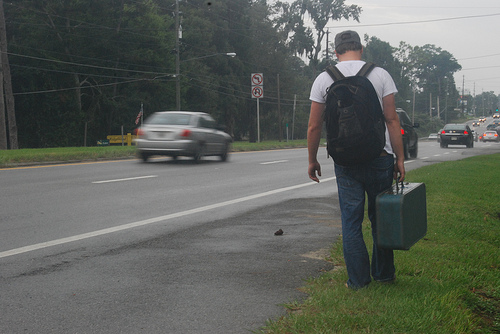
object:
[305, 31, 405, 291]
man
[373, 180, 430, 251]
suitcase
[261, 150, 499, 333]
grass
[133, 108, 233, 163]
car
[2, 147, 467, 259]
line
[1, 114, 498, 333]
road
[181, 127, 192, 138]
light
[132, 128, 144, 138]
light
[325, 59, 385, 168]
backpack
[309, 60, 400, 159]
shirt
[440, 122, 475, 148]
car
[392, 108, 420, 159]
car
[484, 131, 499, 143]
car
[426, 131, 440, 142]
car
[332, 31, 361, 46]
baseball cap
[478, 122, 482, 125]
headlights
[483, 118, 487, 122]
headlights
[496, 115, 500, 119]
headlights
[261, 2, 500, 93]
sky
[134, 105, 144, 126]
flag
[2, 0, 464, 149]
trees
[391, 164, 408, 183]
hand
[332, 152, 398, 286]
jeans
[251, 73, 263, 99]
sign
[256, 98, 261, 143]
pole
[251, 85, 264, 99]
sign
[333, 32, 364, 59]
head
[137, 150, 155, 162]
wheel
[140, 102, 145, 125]
pole